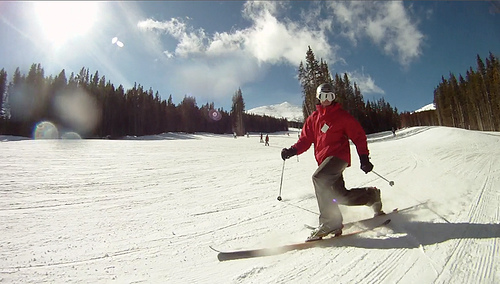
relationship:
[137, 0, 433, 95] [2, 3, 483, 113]
cloud in sky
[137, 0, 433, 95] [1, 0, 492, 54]
cloud in sky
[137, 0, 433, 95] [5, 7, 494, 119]
cloud in sky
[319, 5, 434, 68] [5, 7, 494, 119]
cloud in sky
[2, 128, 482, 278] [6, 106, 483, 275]
snow on hill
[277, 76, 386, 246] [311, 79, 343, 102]
man wearing goggles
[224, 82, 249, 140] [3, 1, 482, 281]
tree in scene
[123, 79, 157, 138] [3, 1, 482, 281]
tree in scene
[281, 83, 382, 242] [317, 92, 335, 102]
man wearing goggles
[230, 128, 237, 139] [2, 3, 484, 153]
person in background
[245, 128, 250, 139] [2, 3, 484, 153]
person in background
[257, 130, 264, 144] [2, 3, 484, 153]
person in background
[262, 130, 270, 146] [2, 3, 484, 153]
person in background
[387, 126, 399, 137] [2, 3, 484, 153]
person in background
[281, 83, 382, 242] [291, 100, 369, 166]
man in coat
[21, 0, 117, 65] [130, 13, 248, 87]
sun in sky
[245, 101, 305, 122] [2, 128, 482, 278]
hill has snow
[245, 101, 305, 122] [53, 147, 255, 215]
hill has white snow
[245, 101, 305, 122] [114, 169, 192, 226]
hill has snow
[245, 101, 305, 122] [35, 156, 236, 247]
hill has snow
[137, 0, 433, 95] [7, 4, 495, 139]
cloud in sky